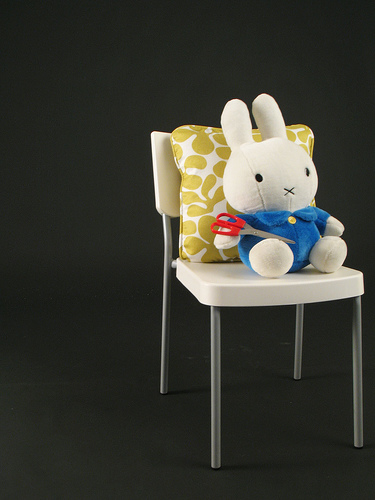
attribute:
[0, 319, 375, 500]
floor — solid, black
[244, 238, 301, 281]
foot — gray, white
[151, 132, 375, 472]
chair — white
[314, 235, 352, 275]
foot — gray, white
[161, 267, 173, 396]
chair leg — long, gray, shiny, grey, tan, silver, metal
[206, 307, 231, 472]
chair leg — long, gray, shiny, grey, tan, silver, metal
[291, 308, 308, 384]
chair leg — long, gray, shiny, grey, tan, silver, metal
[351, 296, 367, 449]
chair leg — long, gray, shiny, grey, tan, silver, metal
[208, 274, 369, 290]
edge — white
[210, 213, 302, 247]
scissors — red, gray, silver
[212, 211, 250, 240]
handle — red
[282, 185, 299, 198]
nose — black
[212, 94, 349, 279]
teddy bear — white, plush, blue, sitting, little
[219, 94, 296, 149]
ears — long, bunny, white, upright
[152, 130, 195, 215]
back — white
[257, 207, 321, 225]
tie — bow, blue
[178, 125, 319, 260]
pillow — gold, white, plush, yellow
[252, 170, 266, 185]
eyes — black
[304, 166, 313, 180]
eyes — black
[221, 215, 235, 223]
holes — finger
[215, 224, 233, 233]
holes — finger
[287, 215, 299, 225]
button — yellow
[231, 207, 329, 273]
clothes — blue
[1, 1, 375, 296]
wall — black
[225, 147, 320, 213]
face — white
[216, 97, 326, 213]
head — white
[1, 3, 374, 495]
room — black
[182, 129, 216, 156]
flower — yellow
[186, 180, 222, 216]
flower — yellow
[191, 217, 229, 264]
flower — yellow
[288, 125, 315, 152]
flower — yellow